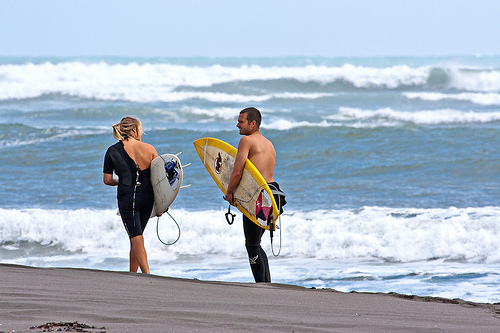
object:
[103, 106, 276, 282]
man/woman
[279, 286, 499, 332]
sea shore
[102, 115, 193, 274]
woman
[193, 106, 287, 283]
man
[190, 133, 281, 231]
surf boards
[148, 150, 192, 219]
surf boards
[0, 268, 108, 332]
beach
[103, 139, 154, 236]
wetsuit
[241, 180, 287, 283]
pants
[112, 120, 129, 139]
pony tail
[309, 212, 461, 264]
wave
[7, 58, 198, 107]
ocean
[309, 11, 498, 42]
sky